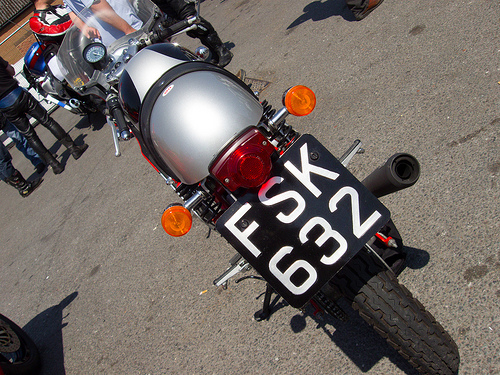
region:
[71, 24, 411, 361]
a mortobike in the picure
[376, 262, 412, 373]
wheels are black in color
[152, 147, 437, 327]
picture taken in the afternoon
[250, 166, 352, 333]
words are written on a blck plate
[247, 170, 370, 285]
words are written in white color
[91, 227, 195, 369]
the floor is gray in color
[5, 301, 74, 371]
shadow of the cr on the flloor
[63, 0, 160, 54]
man pssing infront of th motorbike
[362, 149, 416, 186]
exhauster is black in color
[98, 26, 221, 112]
helmet is black and white in color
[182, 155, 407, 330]
black and white license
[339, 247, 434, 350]
black tire on bike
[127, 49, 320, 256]
orange lights on bike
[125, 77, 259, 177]
grey frame on bike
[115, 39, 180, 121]
black and white helmet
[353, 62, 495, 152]
parking lot is grey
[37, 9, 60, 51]
red and black jacket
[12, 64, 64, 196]
person has black pants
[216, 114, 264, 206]
red taillight on bike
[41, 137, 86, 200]
person has black shoes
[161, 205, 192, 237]
the orange light on the motorcycle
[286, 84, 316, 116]
the orange light on the motorcycle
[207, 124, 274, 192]
the red light on the motorcycle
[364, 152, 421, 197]
the muffler on the motorcycle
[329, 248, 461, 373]
the back tire on the motorcycle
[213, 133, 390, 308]
the license plate on the motorcycle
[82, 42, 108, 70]
the speedometer on the motorcycle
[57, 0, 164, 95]
the windshield on the motorcycle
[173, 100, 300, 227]
the springs on the motorcycle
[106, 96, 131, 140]
the handle on the motorcycle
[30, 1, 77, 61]
Person in black, white and red jacket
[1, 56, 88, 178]
Person wearing black leather pants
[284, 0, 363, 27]
Shadow of person on pavement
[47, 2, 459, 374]
Silver and black motorcycle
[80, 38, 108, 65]
Speedometer on the motorcycle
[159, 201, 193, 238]
Orange tail light on motorcycle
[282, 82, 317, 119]
Orange tailight on motorcycle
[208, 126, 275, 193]
Red tailight on motorcycle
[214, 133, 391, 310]
Black license plate with white writing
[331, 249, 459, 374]
Back tire on motorcycle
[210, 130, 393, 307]
Number plate behind a motorcycle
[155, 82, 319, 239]
Rear lamp behind a motorcycle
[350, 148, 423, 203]
Dark black exhaust pipe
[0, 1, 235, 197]
Riders standing on the tarmac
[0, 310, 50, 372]
Wheel of a vehicle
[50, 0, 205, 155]
Handle bar and other controls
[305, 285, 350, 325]
Rear view of the driving chain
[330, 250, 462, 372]
Tire on the tarmack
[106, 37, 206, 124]
Black and white colored petrol tank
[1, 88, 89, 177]
Tight fitting leather jacket